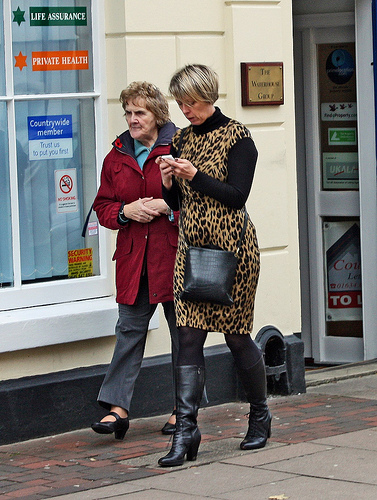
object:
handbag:
[179, 189, 249, 307]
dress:
[161, 106, 259, 335]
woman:
[157, 64, 272, 469]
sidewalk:
[284, 408, 331, 479]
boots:
[157, 354, 272, 469]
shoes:
[91, 404, 199, 441]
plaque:
[240, 62, 284, 108]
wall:
[265, 17, 271, 29]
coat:
[92, 122, 188, 305]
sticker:
[12, 6, 87, 27]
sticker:
[14, 50, 89, 72]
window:
[0, 1, 101, 288]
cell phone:
[159, 154, 175, 163]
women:
[91, 77, 273, 467]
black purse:
[180, 243, 238, 305]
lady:
[91, 81, 195, 439]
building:
[13, 6, 350, 149]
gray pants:
[97, 257, 208, 411]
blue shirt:
[130, 139, 158, 171]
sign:
[27, 114, 73, 160]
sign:
[54, 167, 79, 213]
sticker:
[67, 248, 93, 279]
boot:
[238, 354, 271, 450]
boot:
[157, 366, 206, 468]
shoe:
[89, 413, 129, 441]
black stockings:
[176, 326, 262, 371]